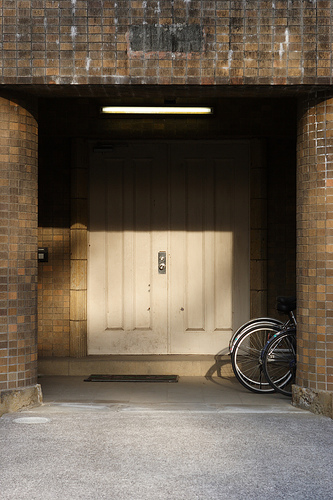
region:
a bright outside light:
[98, 103, 210, 112]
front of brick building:
[0, 1, 331, 415]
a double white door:
[86, 138, 252, 354]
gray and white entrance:
[0, 375, 332, 499]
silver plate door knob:
[157, 249, 166, 272]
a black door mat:
[83, 372, 179, 383]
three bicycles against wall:
[229, 295, 298, 397]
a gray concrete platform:
[37, 355, 294, 377]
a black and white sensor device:
[35, 244, 48, 263]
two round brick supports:
[0, 91, 332, 418]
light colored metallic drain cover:
[12, 415, 49, 424]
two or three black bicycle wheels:
[274, 294, 298, 313]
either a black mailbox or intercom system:
[35, 245, 49, 263]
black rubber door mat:
[81, 372, 180, 383]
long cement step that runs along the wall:
[34, 352, 296, 379]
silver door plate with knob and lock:
[156, 249, 167, 276]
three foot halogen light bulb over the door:
[99, 104, 214, 115]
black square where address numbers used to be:
[125, 21, 203, 55]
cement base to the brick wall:
[0, 382, 44, 414]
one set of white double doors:
[85, 136, 251, 358]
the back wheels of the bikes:
[226, 298, 296, 397]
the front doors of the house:
[92, 142, 247, 351]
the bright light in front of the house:
[102, 103, 211, 116]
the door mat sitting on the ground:
[83, 369, 177, 382]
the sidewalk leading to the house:
[0, 391, 330, 495]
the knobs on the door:
[158, 251, 166, 274]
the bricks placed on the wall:
[3, 4, 325, 73]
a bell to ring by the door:
[35, 247, 45, 260]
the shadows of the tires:
[208, 348, 234, 399]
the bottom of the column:
[290, 384, 331, 409]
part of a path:
[243, 479, 247, 488]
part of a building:
[303, 372, 310, 384]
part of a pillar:
[25, 375, 43, 391]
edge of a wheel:
[239, 367, 244, 384]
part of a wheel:
[239, 329, 243, 339]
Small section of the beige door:
[195, 276, 223, 292]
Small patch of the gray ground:
[171, 463, 189, 480]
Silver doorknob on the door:
[158, 264, 166, 270]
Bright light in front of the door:
[106, 106, 210, 114]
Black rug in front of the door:
[89, 369, 179, 382]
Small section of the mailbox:
[38, 248, 47, 263]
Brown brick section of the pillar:
[312, 133, 328, 153]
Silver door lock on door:
[159, 257, 166, 261]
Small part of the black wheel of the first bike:
[263, 352, 274, 384]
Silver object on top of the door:
[94, 140, 113, 152]